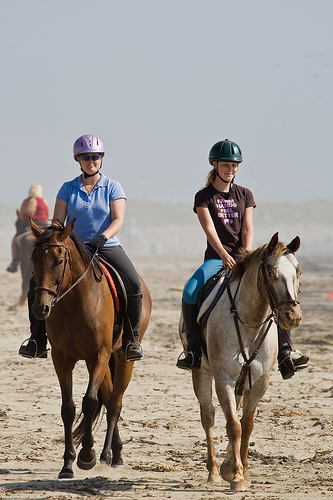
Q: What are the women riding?
A: Horses.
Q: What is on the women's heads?
A: Helmets.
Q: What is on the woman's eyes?
A: Sunglasses.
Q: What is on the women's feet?
A: Riding boots.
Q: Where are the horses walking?
A: Sand.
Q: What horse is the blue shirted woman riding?
A: Horse on right.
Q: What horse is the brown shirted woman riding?
A: Horse on left.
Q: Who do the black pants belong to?
A: A woman.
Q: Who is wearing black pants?
A: A woman.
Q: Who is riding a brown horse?
A: A woman.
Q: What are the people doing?
A: Riding horses.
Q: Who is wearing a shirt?
A: A woman.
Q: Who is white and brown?
A: A horse.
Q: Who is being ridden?
A: A horse.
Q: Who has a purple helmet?
A: A girl.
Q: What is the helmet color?
A: Green.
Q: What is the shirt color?
A: Blue.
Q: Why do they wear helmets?
A: For safety.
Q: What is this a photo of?
A: People on horses.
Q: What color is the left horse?
A: Brown.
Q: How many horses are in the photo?
A: Three.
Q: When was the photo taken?
A: Daytime.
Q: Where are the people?
A: On top of their horse.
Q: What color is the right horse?
A: White.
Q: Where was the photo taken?
A: In a desert.